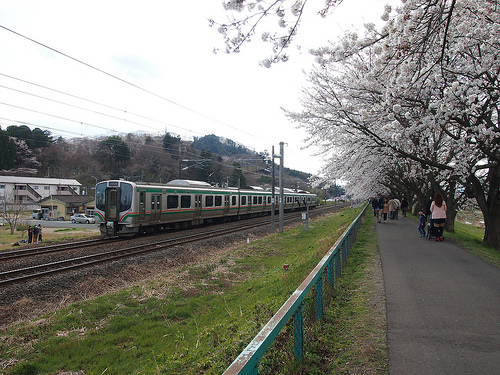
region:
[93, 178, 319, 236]
a green, orange, white and silver passenger train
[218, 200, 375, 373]
a weathered green and chain link fence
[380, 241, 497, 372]
a smooth blacktop walkway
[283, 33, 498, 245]
cherry blossom trees along a walkway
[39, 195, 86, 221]
a yellow house with a grey roof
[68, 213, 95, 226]
a small silver sedan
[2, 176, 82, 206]
white apartment building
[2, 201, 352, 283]
two train track going off into the distance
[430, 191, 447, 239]
a woman in a pink blazer pushing a baby stroller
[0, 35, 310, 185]
utility lines for the electric train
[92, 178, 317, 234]
the train on the tracks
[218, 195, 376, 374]
the fence beside the path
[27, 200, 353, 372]
the grass beside the fence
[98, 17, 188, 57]
the sky is gray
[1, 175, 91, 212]
the buildings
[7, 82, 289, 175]
the power lines above the train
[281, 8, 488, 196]
the white blossoms on the trees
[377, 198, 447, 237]
people on the path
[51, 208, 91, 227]
the car is parked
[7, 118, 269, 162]
the mountain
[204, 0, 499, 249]
a row of cherry trees in full blossom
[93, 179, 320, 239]
passenger trail on a railway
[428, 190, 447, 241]
woman pushing a stroller wearing red shoes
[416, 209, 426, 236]
young child walking with his mother along a pathway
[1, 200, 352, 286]
railway tracks for trains to travel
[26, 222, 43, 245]
group of people standing and conversing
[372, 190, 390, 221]
male and female couple walking on a pedestrian pathway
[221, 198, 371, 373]
light green and rusted partition separating railway tracks and a pedestrian walkway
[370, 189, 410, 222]
group of people walking along a pedestrian pathway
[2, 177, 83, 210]
beige apartment building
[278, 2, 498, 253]
A row of trees with white blossoming flowers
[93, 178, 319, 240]
A train with green and orange stripes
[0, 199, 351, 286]
A railroad track with gravel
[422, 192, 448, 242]
A lady pushing a stroller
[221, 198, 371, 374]
A rusted metal safety fence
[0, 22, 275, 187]
Power lines strung between poles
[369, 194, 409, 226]
A group of people walking on a path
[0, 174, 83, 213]
A residentual dwelling with two outdoor staircases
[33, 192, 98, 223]
A yellow colored building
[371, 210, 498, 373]
A paved pedestrian walkway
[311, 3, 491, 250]
a row of trees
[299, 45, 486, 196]
a bunch of white flowers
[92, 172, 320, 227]
a long train with green and red stripes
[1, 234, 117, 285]
a pair of train tracks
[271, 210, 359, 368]
a green metal fence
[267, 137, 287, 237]
a pair of wood poles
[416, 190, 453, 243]
a woman with her children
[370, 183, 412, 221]
a group of pedestrians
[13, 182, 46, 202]
an outdoor stair case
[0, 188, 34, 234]
a tree without leaves